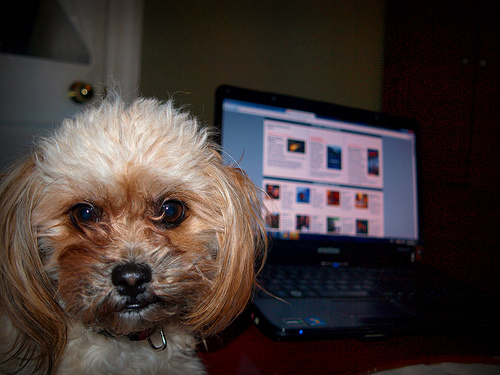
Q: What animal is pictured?
A: A dog.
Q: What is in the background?
A: A computer.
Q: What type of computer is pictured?
A: A laptop.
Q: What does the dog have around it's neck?
A: A collar.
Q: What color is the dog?
A: Tan.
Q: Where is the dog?
A: In front of the laptop.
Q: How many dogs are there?
A: One.